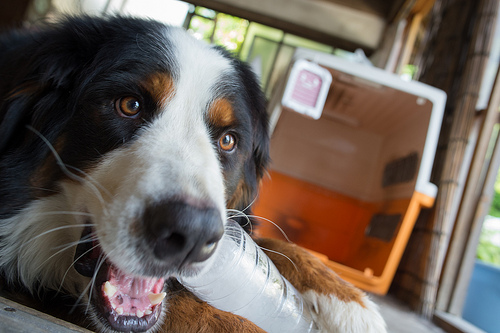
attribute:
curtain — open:
[414, 7, 498, 313]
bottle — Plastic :
[173, 219, 322, 331]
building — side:
[76, 0, 204, 44]